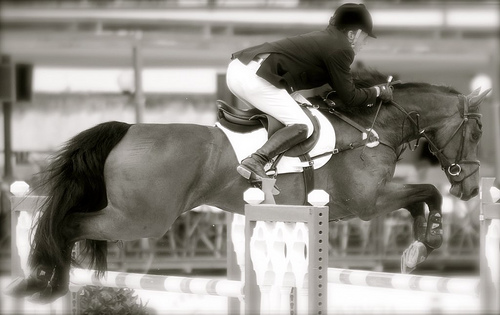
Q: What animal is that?
A: Horse.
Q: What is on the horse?
A: A human.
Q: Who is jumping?
A: Horse.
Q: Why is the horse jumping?
A: Training.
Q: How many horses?
A: One.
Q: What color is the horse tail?
A: Black.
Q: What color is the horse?
A: Brown.